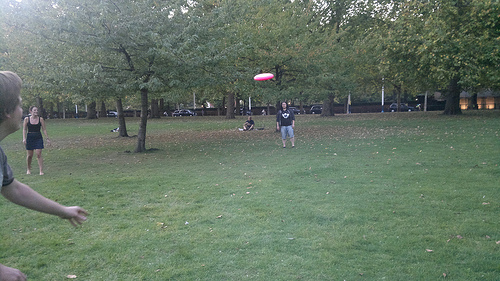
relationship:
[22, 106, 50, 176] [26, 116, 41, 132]
female wearing black shirt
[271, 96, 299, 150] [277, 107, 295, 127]
man in shirt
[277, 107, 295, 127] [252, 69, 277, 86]
shirt waiting for frisbee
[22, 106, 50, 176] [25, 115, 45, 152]
female wearing dress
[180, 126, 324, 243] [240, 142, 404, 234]
grass in field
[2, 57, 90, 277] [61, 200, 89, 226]
man holds out hand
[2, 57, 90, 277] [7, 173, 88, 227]
man with arm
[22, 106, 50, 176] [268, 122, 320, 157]
female wearing jeans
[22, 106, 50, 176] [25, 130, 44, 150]
female wearing skirt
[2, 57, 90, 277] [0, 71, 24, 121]
man has hair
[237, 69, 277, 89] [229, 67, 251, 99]
frisbee flying in air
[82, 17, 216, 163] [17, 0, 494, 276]
tree inside of park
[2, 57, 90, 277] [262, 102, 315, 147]
man playing with man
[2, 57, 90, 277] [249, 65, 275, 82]
man playing with frisbee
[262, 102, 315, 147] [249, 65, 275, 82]
man playing with frisbee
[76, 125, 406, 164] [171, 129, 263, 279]
leaves laying on ground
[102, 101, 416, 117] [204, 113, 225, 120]
parked cars parked along street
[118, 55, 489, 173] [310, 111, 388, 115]
wall next to street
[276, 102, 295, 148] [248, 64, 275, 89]
man playing with frisbee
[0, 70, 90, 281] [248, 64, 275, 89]
man playing with frisbee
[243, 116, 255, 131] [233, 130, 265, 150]
man sitting on top of grass